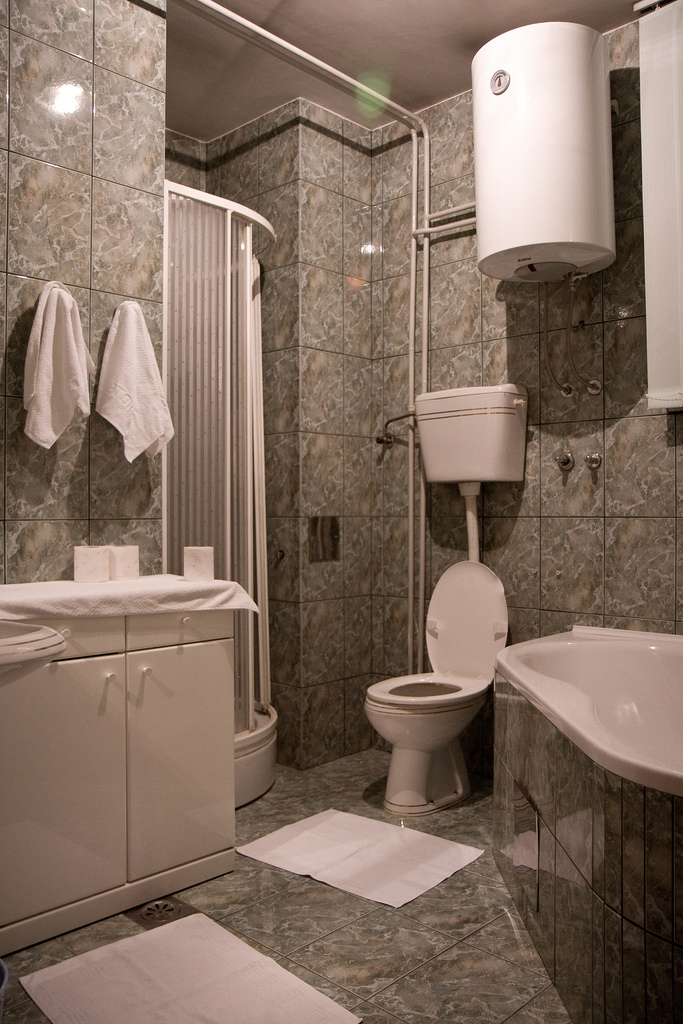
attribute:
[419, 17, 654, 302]
tank — white